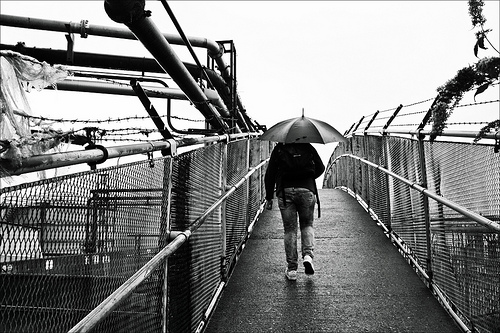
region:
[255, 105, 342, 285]
a person with umbrella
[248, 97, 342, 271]
a person with umbrella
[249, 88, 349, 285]
a person with umbrella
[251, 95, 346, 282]
a person with umbrella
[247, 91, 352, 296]
a person with umbrella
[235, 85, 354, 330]
a person with umbrella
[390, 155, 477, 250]
tall chain link fence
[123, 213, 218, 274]
silver railing on chain link fence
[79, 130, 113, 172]
frames on link fence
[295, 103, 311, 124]
top of black umbrella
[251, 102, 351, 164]
person holding open umbrella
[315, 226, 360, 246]
line across the surface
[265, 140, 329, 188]
black back pack on back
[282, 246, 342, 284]
white sneakers on feet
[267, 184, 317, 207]
pockets on back of blue jeans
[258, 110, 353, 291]
A person is walking on a ramp.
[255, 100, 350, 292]
The person is walking in the rain.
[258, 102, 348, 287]
The person is carrying an umbrella.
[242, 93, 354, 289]
The person is holding an umbrella over their head.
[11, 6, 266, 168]
Metal piping on the left of the person.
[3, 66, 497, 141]
Barbed wire tops the fences.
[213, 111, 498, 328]
The walkway is between two fences.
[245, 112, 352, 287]
The person is walking up the hill.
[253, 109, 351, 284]
The person is wearing jeans.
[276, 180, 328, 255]
a pair of jeans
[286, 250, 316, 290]
a pair of shoes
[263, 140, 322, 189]
a black sweater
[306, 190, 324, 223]
a black string hanging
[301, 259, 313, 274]
the sole of a shoe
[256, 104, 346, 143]
the top of umbrella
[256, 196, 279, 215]
a person's hand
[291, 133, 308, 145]
a black spot on umberalla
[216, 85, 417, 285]
person with an umbrella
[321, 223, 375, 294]
ground under the person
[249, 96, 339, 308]
A person is standing up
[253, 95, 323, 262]
A person walking on a sidewalk.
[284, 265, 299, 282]
person wearing white shoe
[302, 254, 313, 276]
person wearing white shoe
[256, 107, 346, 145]
person holding black umbrella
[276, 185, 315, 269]
person wearing black jeans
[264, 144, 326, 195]
person wearing black jacket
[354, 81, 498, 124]
barbed wire on top of fence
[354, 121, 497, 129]
barbed wire on top of fence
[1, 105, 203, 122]
barbed wire on top of fence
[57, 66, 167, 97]
barbed wire on top of fence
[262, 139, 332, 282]
The person walking up the ramp.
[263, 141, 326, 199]
The black sweater on the person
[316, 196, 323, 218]
The strap hanging from the jacket.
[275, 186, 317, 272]
The jeans on the person.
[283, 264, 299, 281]
The white shoe on the ground.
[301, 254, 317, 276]
The white shoe in the air.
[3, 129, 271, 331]
The chain link fence beside the person.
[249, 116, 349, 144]
The umbrella over the person.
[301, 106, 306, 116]
The point of the umbrella.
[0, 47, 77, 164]
The ripped plastic on the wire.